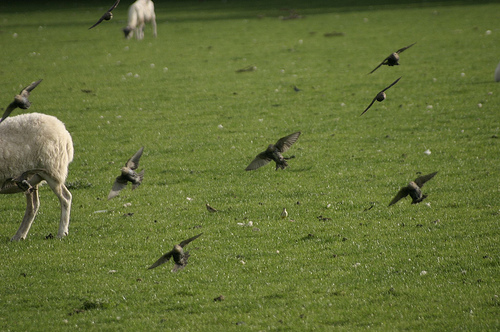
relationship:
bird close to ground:
[145, 228, 201, 278] [1, 172, 496, 329]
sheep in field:
[1, 111, 76, 243] [3, 30, 236, 315]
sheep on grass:
[1, 106, 83, 247] [1, 3, 498, 331]